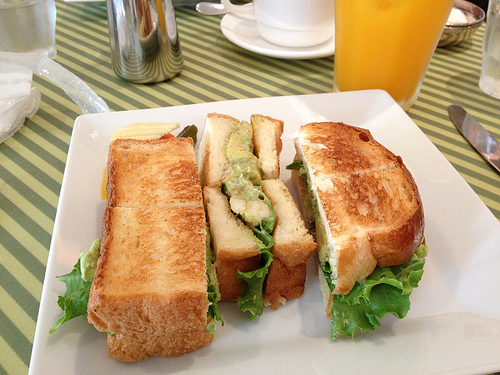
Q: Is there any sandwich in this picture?
A: Yes, there is a sandwich.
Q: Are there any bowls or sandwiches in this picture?
A: Yes, there is a sandwich.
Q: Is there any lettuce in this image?
A: Yes, there is lettuce.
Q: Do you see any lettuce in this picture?
A: Yes, there is lettuce.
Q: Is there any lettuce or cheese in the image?
A: Yes, there is lettuce.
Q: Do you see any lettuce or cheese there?
A: Yes, there is lettuce.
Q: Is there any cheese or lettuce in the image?
A: Yes, there is lettuce.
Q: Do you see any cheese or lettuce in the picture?
A: Yes, there is lettuce.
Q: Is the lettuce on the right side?
A: Yes, the lettuce is on the right of the image.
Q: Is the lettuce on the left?
A: No, the lettuce is on the right of the image.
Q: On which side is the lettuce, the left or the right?
A: The lettuce is on the right of the image.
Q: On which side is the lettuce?
A: The lettuce is on the right of the image.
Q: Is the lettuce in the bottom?
A: Yes, the lettuce is in the bottom of the image.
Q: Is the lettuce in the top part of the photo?
A: No, the lettuce is in the bottom of the image.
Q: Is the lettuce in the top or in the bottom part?
A: The lettuce is in the bottom of the image.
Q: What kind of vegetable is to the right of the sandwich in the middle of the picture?
A: The vegetable is lettuce.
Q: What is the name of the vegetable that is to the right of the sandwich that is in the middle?
A: The vegetable is lettuce.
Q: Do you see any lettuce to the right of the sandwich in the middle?
A: Yes, there is lettuce to the right of the sandwich.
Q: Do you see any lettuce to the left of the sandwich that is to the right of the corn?
A: No, the lettuce is to the right of the sandwich.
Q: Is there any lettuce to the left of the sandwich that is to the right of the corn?
A: No, the lettuce is to the right of the sandwich.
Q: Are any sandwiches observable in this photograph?
A: Yes, there is a sandwich.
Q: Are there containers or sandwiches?
A: Yes, there is a sandwich.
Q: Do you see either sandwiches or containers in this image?
A: Yes, there is a sandwich.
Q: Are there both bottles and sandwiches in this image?
A: No, there is a sandwich but no bottles.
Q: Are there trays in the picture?
A: No, there are no trays.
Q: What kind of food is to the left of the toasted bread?
A: The food is a sandwich.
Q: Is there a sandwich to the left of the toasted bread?
A: Yes, there is a sandwich to the left of the bread.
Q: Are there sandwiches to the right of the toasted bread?
A: No, the sandwich is to the left of the bread.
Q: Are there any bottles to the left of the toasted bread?
A: No, there is a sandwich to the left of the bread.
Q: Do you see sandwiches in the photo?
A: Yes, there is a sandwich.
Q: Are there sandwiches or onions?
A: Yes, there is a sandwich.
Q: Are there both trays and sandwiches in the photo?
A: No, there is a sandwich but no trays.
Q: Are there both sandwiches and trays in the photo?
A: No, there is a sandwich but no trays.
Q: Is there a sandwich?
A: Yes, there is a sandwich.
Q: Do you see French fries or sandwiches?
A: Yes, there is a sandwich.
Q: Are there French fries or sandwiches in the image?
A: Yes, there is a sandwich.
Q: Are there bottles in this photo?
A: No, there are no bottles.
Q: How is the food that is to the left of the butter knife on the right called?
A: The food is a sandwich.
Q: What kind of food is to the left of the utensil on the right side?
A: The food is a sandwich.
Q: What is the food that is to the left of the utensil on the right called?
A: The food is a sandwich.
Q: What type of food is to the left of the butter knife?
A: The food is a sandwich.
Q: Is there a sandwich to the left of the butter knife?
A: Yes, there is a sandwich to the left of the butter knife.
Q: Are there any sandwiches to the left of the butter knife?
A: Yes, there is a sandwich to the left of the butter knife.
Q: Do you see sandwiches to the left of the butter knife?
A: Yes, there is a sandwich to the left of the butter knife.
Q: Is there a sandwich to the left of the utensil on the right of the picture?
A: Yes, there is a sandwich to the left of the butter knife.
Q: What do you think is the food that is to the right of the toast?
A: The food is a sandwich.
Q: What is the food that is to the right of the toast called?
A: The food is a sandwich.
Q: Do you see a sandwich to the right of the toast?
A: Yes, there is a sandwich to the right of the toast.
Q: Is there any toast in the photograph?
A: Yes, there is a toast.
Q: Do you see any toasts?
A: Yes, there is a toast.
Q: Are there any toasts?
A: Yes, there is a toast.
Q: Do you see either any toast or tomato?
A: Yes, there is a toast.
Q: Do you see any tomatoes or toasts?
A: Yes, there is a toast.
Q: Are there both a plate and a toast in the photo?
A: Yes, there are both a toast and a plate.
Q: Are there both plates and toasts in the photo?
A: Yes, there are both a toast and a plate.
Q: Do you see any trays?
A: No, there are no trays.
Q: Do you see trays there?
A: No, there are no trays.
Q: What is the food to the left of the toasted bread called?
A: The food is a toast.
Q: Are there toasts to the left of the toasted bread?
A: Yes, there is a toast to the left of the bread.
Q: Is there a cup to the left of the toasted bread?
A: No, there is a toast to the left of the bread.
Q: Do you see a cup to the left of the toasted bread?
A: No, there is a toast to the left of the bread.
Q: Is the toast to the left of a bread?
A: Yes, the toast is to the left of a bread.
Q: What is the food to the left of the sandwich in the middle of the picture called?
A: The food is a toast.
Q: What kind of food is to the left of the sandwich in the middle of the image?
A: The food is a toast.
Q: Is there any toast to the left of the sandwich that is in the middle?
A: Yes, there is a toast to the left of the sandwich.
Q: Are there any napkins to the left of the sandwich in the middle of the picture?
A: No, there is a toast to the left of the sandwich.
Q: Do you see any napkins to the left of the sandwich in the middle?
A: No, there is a toast to the left of the sandwich.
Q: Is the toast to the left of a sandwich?
A: Yes, the toast is to the left of a sandwich.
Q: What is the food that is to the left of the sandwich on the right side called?
A: The food is a toast.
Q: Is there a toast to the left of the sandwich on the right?
A: Yes, there is a toast to the left of the sandwich.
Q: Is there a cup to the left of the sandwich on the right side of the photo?
A: No, there is a toast to the left of the sandwich.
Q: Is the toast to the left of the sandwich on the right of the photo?
A: Yes, the toast is to the left of the sandwich.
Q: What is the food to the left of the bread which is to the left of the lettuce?
A: The food is a toast.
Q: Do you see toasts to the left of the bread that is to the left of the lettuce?
A: Yes, there is a toast to the left of the bread.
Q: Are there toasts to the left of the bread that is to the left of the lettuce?
A: Yes, there is a toast to the left of the bread.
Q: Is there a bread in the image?
A: Yes, there is a bread.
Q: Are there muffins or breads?
A: Yes, there is a bread.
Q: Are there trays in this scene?
A: No, there are no trays.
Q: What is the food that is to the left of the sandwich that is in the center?
A: The food is a bread.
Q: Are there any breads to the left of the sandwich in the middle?
A: Yes, there is a bread to the left of the sandwich.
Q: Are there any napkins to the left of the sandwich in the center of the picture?
A: No, there is a bread to the left of the sandwich.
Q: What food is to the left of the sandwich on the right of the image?
A: The food is a bread.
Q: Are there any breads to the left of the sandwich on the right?
A: Yes, there is a bread to the left of the sandwich.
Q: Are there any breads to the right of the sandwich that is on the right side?
A: No, the bread is to the left of the sandwich.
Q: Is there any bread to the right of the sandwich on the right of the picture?
A: No, the bread is to the left of the sandwich.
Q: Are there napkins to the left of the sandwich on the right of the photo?
A: No, there is a bread to the left of the sandwich.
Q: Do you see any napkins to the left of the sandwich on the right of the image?
A: No, there is a bread to the left of the sandwich.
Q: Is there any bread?
A: Yes, there is a bread.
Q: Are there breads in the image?
A: Yes, there is a bread.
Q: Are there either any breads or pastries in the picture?
A: Yes, there is a bread.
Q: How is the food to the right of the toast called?
A: The food is a bread.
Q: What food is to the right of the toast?
A: The food is a bread.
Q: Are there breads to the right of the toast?
A: Yes, there is a bread to the right of the toast.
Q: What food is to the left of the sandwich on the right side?
A: The food is a bread.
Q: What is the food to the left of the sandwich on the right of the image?
A: The food is a bread.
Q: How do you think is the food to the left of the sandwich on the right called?
A: The food is a bread.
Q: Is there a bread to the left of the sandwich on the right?
A: Yes, there is a bread to the left of the sandwich.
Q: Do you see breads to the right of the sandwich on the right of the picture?
A: No, the bread is to the left of the sandwich.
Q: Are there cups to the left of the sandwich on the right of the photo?
A: No, there is a bread to the left of the sandwich.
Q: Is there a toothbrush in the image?
A: No, there are no toothbrushes.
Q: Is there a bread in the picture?
A: Yes, there is a bread.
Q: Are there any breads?
A: Yes, there is a bread.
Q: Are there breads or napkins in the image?
A: Yes, there is a bread.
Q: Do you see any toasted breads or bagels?
A: Yes, there is a toasted bread.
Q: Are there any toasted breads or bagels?
A: Yes, there is a toasted bread.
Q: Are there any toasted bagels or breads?
A: Yes, there is a toasted bread.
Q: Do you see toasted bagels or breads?
A: Yes, there is a toasted bread.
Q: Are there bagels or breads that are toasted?
A: Yes, the bread is toasted.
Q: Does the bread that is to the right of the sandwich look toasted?
A: Yes, the bread is toasted.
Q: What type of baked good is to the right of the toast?
A: The food is a bread.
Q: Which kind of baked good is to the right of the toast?
A: The food is a bread.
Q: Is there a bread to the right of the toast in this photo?
A: Yes, there is a bread to the right of the toast.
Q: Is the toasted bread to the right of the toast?
A: Yes, the bread is to the right of the toast.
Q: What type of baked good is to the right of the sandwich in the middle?
A: The food is a bread.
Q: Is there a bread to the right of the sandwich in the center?
A: Yes, there is a bread to the right of the sandwich.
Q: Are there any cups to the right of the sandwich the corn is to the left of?
A: No, there is a bread to the right of the sandwich.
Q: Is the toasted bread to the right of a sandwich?
A: Yes, the bread is to the right of a sandwich.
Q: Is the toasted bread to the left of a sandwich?
A: No, the bread is to the right of a sandwich.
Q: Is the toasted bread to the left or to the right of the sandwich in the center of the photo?
A: The bread is to the right of the sandwich.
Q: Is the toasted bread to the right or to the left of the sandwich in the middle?
A: The bread is to the right of the sandwich.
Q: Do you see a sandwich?
A: Yes, there is a sandwich.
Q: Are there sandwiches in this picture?
A: Yes, there is a sandwich.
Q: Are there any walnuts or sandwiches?
A: Yes, there is a sandwich.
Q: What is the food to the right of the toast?
A: The food is a sandwich.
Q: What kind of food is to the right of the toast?
A: The food is a sandwich.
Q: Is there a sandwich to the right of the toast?
A: Yes, there is a sandwich to the right of the toast.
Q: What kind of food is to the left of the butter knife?
A: The food is a sandwich.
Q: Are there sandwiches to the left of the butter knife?
A: Yes, there is a sandwich to the left of the butter knife.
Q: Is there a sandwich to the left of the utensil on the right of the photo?
A: Yes, there is a sandwich to the left of the butter knife.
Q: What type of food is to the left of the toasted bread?
A: The food is a sandwich.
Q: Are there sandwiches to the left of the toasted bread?
A: Yes, there is a sandwich to the left of the bread.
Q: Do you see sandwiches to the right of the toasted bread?
A: No, the sandwich is to the left of the bread.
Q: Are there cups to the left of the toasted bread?
A: No, there is a sandwich to the left of the bread.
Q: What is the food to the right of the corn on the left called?
A: The food is a sandwich.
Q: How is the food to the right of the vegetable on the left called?
A: The food is a sandwich.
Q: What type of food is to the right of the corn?
A: The food is a sandwich.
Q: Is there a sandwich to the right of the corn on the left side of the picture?
A: Yes, there is a sandwich to the right of the corn.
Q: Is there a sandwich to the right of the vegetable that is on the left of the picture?
A: Yes, there is a sandwich to the right of the corn.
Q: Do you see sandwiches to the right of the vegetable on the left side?
A: Yes, there is a sandwich to the right of the corn.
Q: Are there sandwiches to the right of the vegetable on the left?
A: Yes, there is a sandwich to the right of the corn.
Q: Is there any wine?
A: No, there is no wine.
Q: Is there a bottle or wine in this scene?
A: No, there are no wine or bottles.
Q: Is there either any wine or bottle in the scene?
A: No, there are no wine or bottles.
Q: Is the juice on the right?
A: Yes, the juice is on the right of the image.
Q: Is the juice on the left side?
A: No, the juice is on the right of the image.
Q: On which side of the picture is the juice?
A: The juice is on the right of the image.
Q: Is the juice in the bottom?
A: No, the juice is in the top of the image.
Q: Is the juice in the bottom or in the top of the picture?
A: The juice is in the top of the image.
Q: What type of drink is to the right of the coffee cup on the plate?
A: The drink is juice.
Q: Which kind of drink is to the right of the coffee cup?
A: The drink is juice.